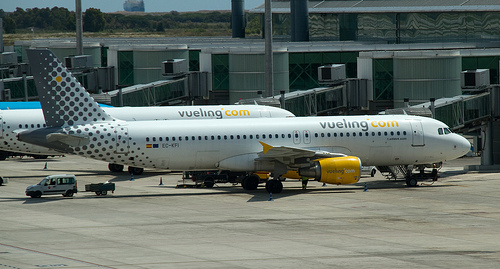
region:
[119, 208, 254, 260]
Grey colored airport tarmac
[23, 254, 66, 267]
Writing on airport ground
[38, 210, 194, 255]
Big squares on ground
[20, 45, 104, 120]
Circle patterned airplane tail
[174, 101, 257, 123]
vueling com airline plane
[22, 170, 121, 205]
Vehicle dragging a trolley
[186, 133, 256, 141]
Windows on airplane side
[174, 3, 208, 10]
Clear blue cloudless sky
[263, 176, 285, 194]
Black colored plane wheels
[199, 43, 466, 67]
White and green colored buildings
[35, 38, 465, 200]
white plane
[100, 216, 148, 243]
gray and white airport pavement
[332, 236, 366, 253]
gray and white airport pavement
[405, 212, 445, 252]
gray and white airport pavement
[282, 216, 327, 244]
gray and white airport pavement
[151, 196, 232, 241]
gray and white airport pavement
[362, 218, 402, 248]
gray and white airport pavement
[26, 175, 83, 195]
a white van by the plane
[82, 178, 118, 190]
the trailer the van is pulling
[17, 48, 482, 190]
an airplane on the ground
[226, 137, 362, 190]
the wing on the airplane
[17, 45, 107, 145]
the tail wing on the airplane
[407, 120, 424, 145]
a door on the plane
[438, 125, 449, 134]
the windshield on the plane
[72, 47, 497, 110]
a building in front of the planes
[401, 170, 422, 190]
the tire on the plane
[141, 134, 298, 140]
windows on the plane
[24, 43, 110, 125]
Vertical stabilizer on a plane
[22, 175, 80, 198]
A white car parked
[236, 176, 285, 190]
Landing gear underneath a plane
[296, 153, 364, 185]
An engine on a plane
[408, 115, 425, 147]
A door on a plane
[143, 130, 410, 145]
Windows on the side of a window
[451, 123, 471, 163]
Nose on a plane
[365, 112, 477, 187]
Front end of a plane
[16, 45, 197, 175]
Back end of a plane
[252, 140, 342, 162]
Wing of a plane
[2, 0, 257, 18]
blue of daytime sky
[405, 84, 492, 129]
ramp for boarding passengers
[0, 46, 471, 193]
two planes on tarmac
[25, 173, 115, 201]
vehicle with attached cart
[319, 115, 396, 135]
gray and yellow word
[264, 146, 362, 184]
plane engine under wing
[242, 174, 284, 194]
wheels of landing gear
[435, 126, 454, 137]
windows on plane cockpit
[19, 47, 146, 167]
design on back of plane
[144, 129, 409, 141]
row of windows on plane